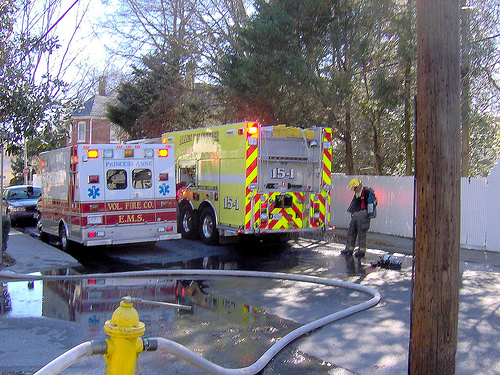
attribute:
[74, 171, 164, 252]
ambulence — with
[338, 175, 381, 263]
firefighter — without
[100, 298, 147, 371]
fire hydrant — yellow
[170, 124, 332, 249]
fire truck — yellow, red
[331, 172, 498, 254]
fence — white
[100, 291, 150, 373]
hydrant — with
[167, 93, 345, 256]
fire truck — parked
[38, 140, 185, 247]
ambulence — parked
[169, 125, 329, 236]
firetruck — parked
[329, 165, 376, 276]
fireman — with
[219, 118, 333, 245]
firetruck — by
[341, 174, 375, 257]
firefighter — by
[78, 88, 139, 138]
brick house — red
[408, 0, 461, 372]
post — wooden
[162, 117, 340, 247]
firetruck — by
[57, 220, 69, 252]
wheel — on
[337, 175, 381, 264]
fireman — looking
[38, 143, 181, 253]
ambulance — white, red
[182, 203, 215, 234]
wheels — on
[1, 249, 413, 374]
water — large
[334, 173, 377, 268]
firefighter — waiting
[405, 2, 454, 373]
telephone pole — wooden